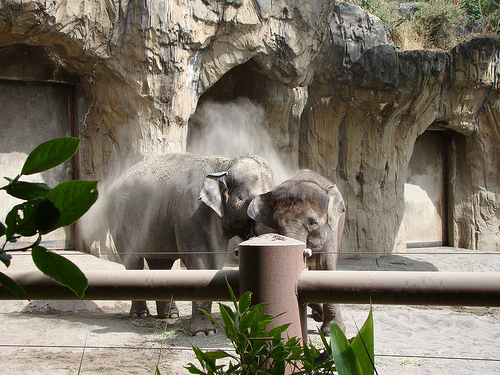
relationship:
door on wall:
[404, 119, 446, 248] [10, 2, 498, 254]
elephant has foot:
[111, 146, 268, 337] [187, 239, 216, 344]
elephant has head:
[111, 146, 268, 337] [216, 156, 272, 248]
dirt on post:
[250, 229, 289, 246] [239, 232, 314, 375]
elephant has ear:
[111, 146, 268, 337] [201, 168, 232, 219]